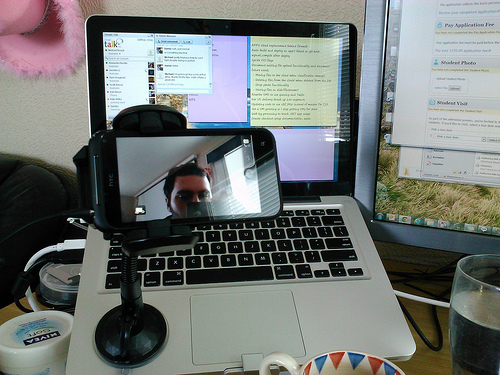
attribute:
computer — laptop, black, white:
[83, 19, 374, 288]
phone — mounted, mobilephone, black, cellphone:
[92, 132, 281, 220]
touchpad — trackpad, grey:
[199, 298, 299, 347]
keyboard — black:
[218, 231, 359, 270]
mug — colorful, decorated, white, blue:
[267, 350, 399, 374]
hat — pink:
[1, 1, 83, 63]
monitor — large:
[364, 3, 498, 260]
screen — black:
[92, 19, 354, 194]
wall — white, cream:
[6, 90, 83, 144]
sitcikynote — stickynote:
[250, 42, 340, 130]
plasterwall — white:
[9, 81, 91, 124]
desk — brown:
[3, 194, 499, 370]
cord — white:
[28, 237, 87, 253]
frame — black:
[103, 17, 357, 38]